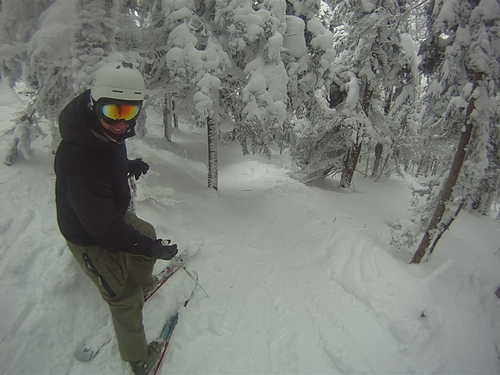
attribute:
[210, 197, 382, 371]
snow — white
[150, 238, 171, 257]
gloves — black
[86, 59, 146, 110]
helmet — white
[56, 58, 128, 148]
hood — black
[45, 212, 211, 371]
pants — tan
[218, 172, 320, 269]
snow — white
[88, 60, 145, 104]
hard hat — white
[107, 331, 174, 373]
boot — gray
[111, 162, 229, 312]
snow — white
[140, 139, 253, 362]
snow — white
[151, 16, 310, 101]
snow — white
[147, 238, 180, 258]
hand — gloved